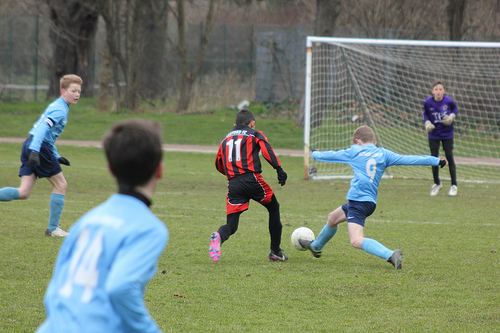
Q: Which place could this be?
A: It is a field.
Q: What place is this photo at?
A: It is at the field.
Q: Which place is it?
A: It is a field.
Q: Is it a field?
A: Yes, it is a field.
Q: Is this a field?
A: Yes, it is a field.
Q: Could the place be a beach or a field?
A: It is a field.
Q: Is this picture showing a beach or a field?
A: It is showing a field.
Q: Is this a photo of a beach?
A: No, the picture is showing a field.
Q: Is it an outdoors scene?
A: Yes, it is outdoors.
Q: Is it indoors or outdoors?
A: It is outdoors.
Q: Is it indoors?
A: No, it is outdoors.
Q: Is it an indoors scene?
A: No, it is outdoors.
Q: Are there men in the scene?
A: No, there are no men.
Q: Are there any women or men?
A: No, there are no men or women.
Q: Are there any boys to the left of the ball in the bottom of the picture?
A: Yes, there is a boy to the left of the ball.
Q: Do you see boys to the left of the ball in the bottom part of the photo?
A: Yes, there is a boy to the left of the ball.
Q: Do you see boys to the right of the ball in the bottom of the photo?
A: No, the boy is to the left of the ball.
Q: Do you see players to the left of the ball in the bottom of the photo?
A: No, there is a boy to the left of the ball.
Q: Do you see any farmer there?
A: No, there are no farmers.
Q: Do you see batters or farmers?
A: No, there are no farmers or batters.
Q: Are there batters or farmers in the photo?
A: No, there are no farmers or batters.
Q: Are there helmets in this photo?
A: No, there are no helmets.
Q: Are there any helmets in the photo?
A: No, there are no helmets.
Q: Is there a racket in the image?
A: No, there are no rackets.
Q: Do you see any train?
A: No, there are no trains.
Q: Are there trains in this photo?
A: No, there are no trains.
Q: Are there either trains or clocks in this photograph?
A: No, there are no trains or clocks.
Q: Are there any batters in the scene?
A: No, there are no batters.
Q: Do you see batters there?
A: No, there are no batters.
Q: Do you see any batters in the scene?
A: No, there are no batters.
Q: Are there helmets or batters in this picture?
A: No, there are no batters or helmets.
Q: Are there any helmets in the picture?
A: No, there are no helmets.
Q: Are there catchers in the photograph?
A: No, there are no catchers.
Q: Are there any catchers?
A: No, there are no catchers.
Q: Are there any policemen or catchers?
A: No, there are no catchers or policemen.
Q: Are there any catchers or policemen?
A: No, there are no catchers or policemen.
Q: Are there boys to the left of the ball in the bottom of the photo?
A: Yes, there is a boy to the left of the ball.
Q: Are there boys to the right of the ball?
A: No, the boy is to the left of the ball.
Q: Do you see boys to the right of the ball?
A: No, the boy is to the left of the ball.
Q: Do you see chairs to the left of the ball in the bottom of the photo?
A: No, there is a boy to the left of the ball.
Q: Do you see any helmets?
A: No, there are no helmets.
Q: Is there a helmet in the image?
A: No, there are no helmets.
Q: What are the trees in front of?
A: The trees are in front of the pond.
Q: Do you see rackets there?
A: No, there are no rackets.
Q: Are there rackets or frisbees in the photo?
A: No, there are no rackets or frisbees.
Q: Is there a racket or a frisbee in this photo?
A: No, there are no rackets or frisbees.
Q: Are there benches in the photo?
A: No, there are no benches.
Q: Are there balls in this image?
A: Yes, there is a ball.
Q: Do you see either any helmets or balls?
A: Yes, there is a ball.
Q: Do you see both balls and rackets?
A: No, there is a ball but no rackets.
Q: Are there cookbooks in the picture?
A: No, there are no cookbooks.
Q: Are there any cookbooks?
A: No, there are no cookbooks.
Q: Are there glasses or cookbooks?
A: No, there are no cookbooks or glasses.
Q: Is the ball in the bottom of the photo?
A: Yes, the ball is in the bottom of the image.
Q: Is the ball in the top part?
A: No, the ball is in the bottom of the image.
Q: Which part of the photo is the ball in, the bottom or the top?
A: The ball is in the bottom of the image.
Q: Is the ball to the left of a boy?
A: No, the ball is to the right of a boy.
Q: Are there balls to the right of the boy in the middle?
A: Yes, there is a ball to the right of the boy.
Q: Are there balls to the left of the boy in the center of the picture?
A: No, the ball is to the right of the boy.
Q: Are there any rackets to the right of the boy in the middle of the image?
A: No, there is a ball to the right of the boy.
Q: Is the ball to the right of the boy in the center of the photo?
A: Yes, the ball is to the right of the boy.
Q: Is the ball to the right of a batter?
A: No, the ball is to the right of the boy.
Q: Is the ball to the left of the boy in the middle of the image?
A: No, the ball is to the right of the boy.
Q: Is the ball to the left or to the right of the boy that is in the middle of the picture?
A: The ball is to the right of the boy.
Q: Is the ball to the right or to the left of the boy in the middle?
A: The ball is to the right of the boy.